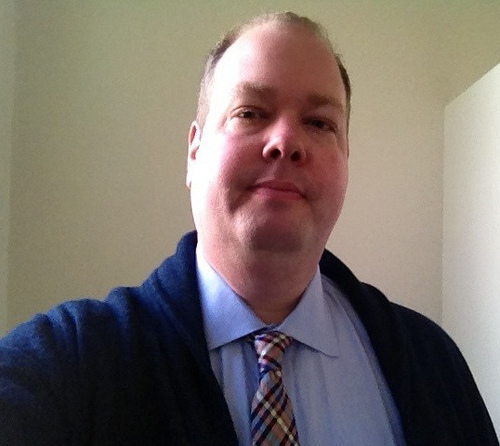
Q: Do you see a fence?
A: No, there are no fences.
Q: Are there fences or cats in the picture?
A: No, there are no fences or cats.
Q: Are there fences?
A: No, there are no fences.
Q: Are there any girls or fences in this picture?
A: No, there are no fences or girls.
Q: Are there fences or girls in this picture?
A: No, there are no fences or girls.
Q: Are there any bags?
A: No, there are no bags.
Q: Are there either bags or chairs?
A: No, there are no bags or chairs.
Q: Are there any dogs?
A: No, there are no dogs.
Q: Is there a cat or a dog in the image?
A: No, there are no dogs or cats.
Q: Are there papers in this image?
A: No, there are no papers.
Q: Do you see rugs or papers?
A: No, there are no papers or rugs.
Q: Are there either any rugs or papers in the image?
A: No, there are no papers or rugs.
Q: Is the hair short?
A: Yes, the hair is short.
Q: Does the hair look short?
A: Yes, the hair is short.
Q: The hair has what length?
A: The hair is short.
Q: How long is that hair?
A: The hair is short.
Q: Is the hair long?
A: No, the hair is short.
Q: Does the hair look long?
A: No, the hair is short.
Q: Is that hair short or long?
A: The hair is short.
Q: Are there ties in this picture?
A: Yes, there is a tie.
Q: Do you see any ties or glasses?
A: Yes, there is a tie.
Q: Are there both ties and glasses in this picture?
A: No, there is a tie but no glasses.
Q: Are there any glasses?
A: No, there are no glasses.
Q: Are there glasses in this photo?
A: No, there are no glasses.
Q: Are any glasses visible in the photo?
A: No, there are no glasses.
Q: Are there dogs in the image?
A: No, there are no dogs.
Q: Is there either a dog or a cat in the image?
A: No, there are no dogs or cats.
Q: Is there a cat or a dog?
A: No, there are no dogs or cats.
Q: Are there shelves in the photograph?
A: No, there are no shelves.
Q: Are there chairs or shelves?
A: No, there are no shelves or chairs.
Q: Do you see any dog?
A: No, there are no dogs.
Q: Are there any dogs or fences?
A: No, there are no dogs or fences.